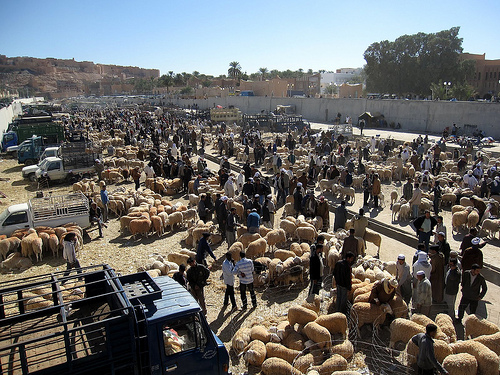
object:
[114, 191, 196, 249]
sheep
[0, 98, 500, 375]
market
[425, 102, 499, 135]
wall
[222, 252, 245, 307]
person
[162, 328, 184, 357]
clothes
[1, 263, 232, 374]
truck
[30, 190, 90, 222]
cage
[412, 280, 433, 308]
shirt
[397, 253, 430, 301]
hats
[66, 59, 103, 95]
mountain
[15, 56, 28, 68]
rocks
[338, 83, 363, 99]
building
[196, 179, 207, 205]
people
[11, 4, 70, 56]
sky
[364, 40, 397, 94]
trees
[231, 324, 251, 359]
herd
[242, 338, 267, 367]
sheep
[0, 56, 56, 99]
hills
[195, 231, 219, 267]
man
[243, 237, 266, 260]
herd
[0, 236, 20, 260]
sheep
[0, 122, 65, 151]
truck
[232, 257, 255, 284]
shirt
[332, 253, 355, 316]
man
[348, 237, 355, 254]
brown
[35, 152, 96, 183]
truck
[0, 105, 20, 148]
fence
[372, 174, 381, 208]
people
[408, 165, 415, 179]
sheep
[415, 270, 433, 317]
men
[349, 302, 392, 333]
sheep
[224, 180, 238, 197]
shirt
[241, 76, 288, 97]
building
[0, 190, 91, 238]
truck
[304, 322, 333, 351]
sheep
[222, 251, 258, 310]
couple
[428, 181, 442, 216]
people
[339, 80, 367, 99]
houses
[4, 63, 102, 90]
distance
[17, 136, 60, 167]
trucks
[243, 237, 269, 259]
sheep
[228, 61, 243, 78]
trees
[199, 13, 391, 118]
background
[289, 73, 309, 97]
buildings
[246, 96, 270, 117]
fence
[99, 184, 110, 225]
crowd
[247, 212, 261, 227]
shirt